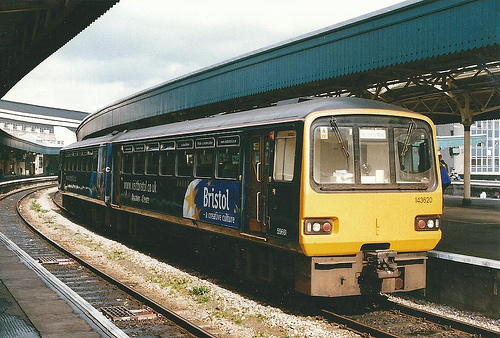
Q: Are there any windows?
A: Yes, there is a window.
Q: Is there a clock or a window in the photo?
A: Yes, there is a window.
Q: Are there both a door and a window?
A: Yes, there are both a window and a door.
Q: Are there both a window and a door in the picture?
A: Yes, there are both a window and a door.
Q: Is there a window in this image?
A: Yes, there is a window.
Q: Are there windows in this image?
A: Yes, there is a window.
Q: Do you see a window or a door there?
A: Yes, there is a window.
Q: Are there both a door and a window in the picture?
A: Yes, there are both a window and a door.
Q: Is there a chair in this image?
A: No, there are no chairs.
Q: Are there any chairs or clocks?
A: No, there are no chairs or clocks.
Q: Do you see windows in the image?
A: Yes, there is a window.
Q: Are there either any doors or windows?
A: Yes, there is a window.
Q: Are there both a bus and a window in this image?
A: No, there is a window but no buses.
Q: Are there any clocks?
A: No, there are no clocks.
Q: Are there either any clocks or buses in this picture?
A: No, there are no clocks or buses.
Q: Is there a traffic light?
A: No, there are no traffic lights.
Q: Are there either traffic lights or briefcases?
A: No, there are no traffic lights or briefcases.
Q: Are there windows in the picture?
A: Yes, there is a window.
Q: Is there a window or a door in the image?
A: Yes, there is a window.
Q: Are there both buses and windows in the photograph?
A: No, there is a window but no buses.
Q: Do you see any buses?
A: No, there are no buses.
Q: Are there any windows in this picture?
A: Yes, there is a window.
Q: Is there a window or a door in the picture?
A: Yes, there is a window.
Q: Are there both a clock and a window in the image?
A: No, there is a window but no clocks.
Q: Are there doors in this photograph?
A: Yes, there is a door.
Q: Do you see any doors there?
A: Yes, there is a door.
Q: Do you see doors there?
A: Yes, there is a door.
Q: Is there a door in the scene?
A: Yes, there is a door.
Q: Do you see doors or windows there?
A: Yes, there is a door.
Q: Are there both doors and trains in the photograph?
A: Yes, there are both a door and a train.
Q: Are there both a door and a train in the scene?
A: Yes, there are both a door and a train.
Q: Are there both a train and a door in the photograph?
A: Yes, there are both a door and a train.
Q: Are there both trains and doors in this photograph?
A: Yes, there are both a door and a train.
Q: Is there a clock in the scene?
A: No, there are no clocks.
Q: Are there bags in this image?
A: No, there are no bags.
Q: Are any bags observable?
A: No, there are no bags.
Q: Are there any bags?
A: No, there are no bags.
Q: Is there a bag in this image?
A: No, there are no bags.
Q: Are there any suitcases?
A: No, there are no suitcases.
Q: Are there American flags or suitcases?
A: No, there are no suitcases or American flags.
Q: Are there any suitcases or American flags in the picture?
A: No, there are no suitcases or American flags.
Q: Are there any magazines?
A: No, there are no magazines.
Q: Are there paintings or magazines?
A: No, there are no magazines or paintings.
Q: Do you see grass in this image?
A: Yes, there is grass.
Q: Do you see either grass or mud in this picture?
A: Yes, there is grass.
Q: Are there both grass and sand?
A: No, there is grass but no sand.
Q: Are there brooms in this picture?
A: No, there are no brooms.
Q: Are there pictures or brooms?
A: No, there are no brooms or pictures.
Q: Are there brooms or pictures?
A: No, there are no brooms or pictures.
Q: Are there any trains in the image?
A: Yes, there is a train.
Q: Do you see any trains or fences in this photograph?
A: Yes, there is a train.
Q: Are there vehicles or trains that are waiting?
A: Yes, the train is waiting.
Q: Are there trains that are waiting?
A: Yes, there is a train that is waiting.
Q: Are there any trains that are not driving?
A: Yes, there is a train that is waiting.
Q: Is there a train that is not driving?
A: Yes, there is a train that is waiting.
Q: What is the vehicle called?
A: The vehicle is a train.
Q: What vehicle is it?
A: The vehicle is a train.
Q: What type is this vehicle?
A: This is a train.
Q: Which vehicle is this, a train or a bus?
A: This is a train.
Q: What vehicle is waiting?
A: The vehicle is a train.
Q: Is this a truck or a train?
A: This is a train.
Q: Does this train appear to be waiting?
A: Yes, the train is waiting.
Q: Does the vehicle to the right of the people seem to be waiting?
A: Yes, the train is waiting.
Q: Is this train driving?
A: No, the train is waiting.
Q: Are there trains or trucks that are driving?
A: No, there is a train but it is waiting.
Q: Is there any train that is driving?
A: No, there is a train but it is waiting.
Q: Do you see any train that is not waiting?
A: No, there is a train but it is waiting.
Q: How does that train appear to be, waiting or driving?
A: The train is waiting.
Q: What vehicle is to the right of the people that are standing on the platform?
A: The vehicle is a train.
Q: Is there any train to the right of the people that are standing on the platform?
A: Yes, there is a train to the right of the people.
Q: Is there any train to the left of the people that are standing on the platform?
A: No, the train is to the right of the people.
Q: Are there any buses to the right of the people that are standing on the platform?
A: No, there is a train to the right of the people.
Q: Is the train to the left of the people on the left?
A: No, the train is to the right of the people.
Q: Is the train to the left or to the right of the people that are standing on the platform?
A: The train is to the right of the people.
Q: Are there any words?
A: Yes, there are words.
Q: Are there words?
A: Yes, there are words.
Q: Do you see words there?
A: Yes, there are words.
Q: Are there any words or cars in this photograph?
A: Yes, there are words.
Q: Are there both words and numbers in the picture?
A: Yes, there are both words and numbers.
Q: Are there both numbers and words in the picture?
A: Yes, there are both words and numbers.